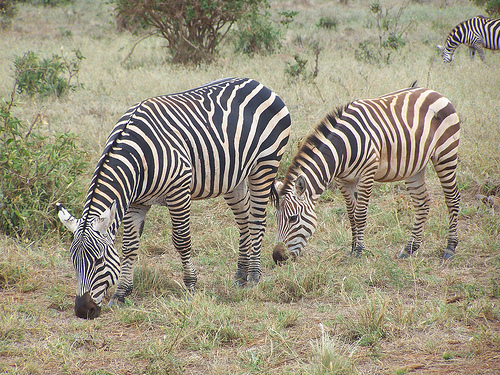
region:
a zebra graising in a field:
[50, 73, 291, 318]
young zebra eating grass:
[276, 81, 474, 272]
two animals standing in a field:
[43, 78, 473, 320]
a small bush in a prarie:
[112, 0, 272, 64]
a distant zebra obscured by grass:
[430, 17, 498, 65]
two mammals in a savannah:
[46, 73, 467, 321]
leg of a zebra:
[433, 163, 468, 278]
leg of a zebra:
[386, 181, 428, 258]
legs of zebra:
[341, 193, 364, 263]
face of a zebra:
[270, 177, 322, 279]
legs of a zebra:
[207, 195, 277, 300]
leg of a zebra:
[165, 200, 202, 300]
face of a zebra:
[38, 193, 124, 328]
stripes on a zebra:
[420, 91, 453, 149]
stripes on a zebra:
[360, 125, 411, 172]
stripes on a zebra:
[242, 107, 270, 188]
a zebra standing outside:
[36, 95, 357, 344]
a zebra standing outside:
[296, 58, 498, 260]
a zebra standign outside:
[407, 8, 492, 65]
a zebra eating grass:
[39, 33, 329, 373]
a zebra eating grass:
[294, 91, 497, 308]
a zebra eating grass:
[432, 8, 485, 96]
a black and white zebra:
[277, 73, 474, 253]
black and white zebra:
[79, 74, 324, 369]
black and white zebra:
[429, 9, 487, 90]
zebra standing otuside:
[67, 55, 286, 307]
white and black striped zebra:
[3, 83, 284, 315]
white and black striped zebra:
[265, 82, 469, 279]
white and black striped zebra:
[438, 8, 496, 62]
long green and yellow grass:
[160, 317, 186, 340]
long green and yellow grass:
[270, 312, 340, 348]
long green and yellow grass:
[352, 300, 409, 337]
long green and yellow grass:
[107, 326, 140, 359]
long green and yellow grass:
[436, 296, 468, 336]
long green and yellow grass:
[209, 331, 226, 338]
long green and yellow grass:
[260, 311, 304, 351]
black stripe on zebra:
[436, 142, 460, 159]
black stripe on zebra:
[421, 101, 451, 163]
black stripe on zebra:
[408, 88, 427, 122]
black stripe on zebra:
[323, 132, 350, 177]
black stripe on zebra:
[307, 147, 329, 189]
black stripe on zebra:
[248, 175, 275, 185]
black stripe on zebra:
[249, 163, 276, 175]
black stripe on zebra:
[263, 135, 290, 170]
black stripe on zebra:
[262, 113, 293, 151]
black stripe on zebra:
[245, 96, 282, 166]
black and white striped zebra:
[46, 80, 277, 314]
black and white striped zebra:
[263, 80, 465, 254]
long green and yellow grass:
[135, 335, 155, 357]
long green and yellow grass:
[335, 328, 379, 358]